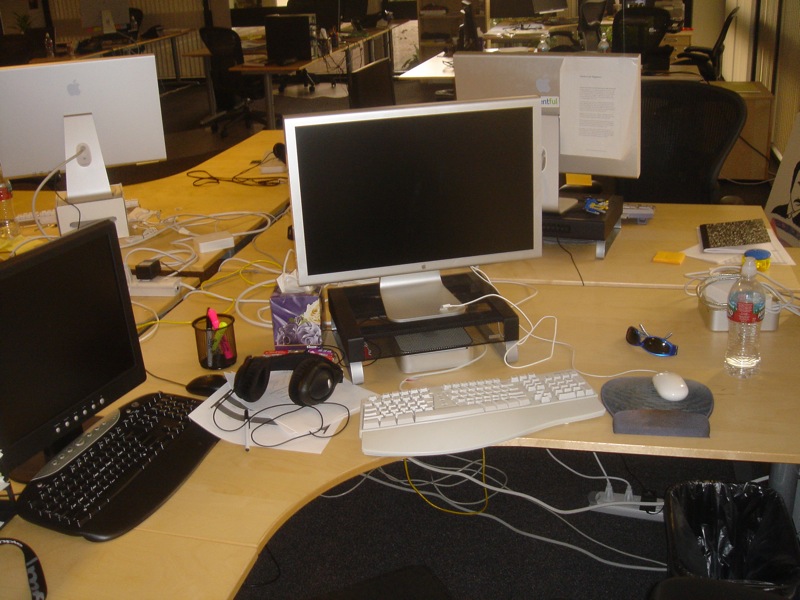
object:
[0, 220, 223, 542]
monitor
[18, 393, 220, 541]
keyboard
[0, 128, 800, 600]
desk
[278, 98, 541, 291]
monitor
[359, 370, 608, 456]
keyboard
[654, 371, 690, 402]
mouse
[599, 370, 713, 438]
pad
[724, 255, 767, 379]
bottle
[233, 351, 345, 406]
headphones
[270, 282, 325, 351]
kleenex box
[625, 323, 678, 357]
sunglasses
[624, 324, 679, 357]
pair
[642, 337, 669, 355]
lenses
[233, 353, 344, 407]
pair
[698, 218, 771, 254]
notebook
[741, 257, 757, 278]
lid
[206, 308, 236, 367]
highlighter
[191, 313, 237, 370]
cup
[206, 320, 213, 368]
highlighter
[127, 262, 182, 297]
surge protector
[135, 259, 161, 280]
cord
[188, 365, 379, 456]
paper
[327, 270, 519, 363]
stand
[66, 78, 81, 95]
apple logo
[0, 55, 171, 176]
monitor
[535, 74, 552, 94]
apple logo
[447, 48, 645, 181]
monitor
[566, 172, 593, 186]
post-it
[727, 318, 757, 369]
spring water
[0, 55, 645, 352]
desktop computers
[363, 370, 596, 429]
ten key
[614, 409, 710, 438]
wrist rest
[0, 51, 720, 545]
collection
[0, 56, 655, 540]
work stations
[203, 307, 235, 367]
pens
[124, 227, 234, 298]
electricity